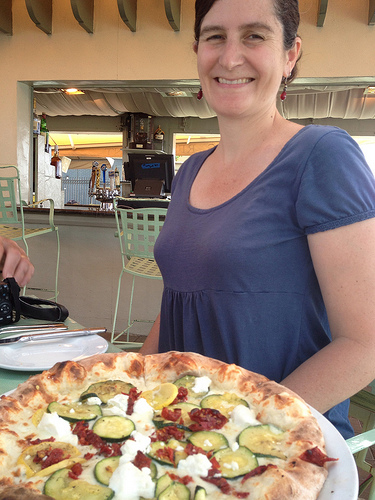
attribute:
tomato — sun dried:
[42, 384, 319, 494]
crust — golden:
[6, 348, 324, 500]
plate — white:
[0, 319, 108, 374]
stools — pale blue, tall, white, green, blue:
[4, 157, 182, 360]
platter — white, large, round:
[303, 387, 363, 500]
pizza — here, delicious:
[2, 348, 325, 500]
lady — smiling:
[119, 0, 372, 438]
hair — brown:
[188, 1, 303, 91]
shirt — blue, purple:
[149, 120, 375, 412]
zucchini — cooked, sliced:
[34, 376, 281, 500]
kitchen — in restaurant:
[28, 85, 375, 217]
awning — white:
[27, 85, 375, 132]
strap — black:
[4, 277, 75, 337]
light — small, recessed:
[64, 85, 81, 101]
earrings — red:
[195, 79, 291, 102]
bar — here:
[18, 195, 171, 226]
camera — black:
[2, 274, 18, 324]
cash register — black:
[123, 157, 172, 202]